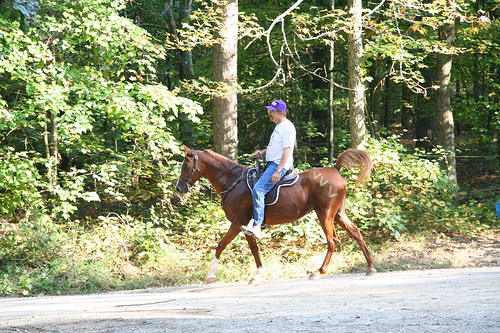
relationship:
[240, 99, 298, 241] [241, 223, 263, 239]
man has shoe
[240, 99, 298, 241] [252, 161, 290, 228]
man has leg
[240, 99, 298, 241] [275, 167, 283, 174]
man wearing watch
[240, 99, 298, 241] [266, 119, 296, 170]
man wearing shirt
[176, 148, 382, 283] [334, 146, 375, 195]
horse has tail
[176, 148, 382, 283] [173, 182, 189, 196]
horse has nose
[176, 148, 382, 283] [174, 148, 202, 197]
horse has head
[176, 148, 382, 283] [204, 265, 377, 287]
horse has hooves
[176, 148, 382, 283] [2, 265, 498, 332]
horse on gravel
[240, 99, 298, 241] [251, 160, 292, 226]
man wearing jeans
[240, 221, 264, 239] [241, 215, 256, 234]
foot in stirrups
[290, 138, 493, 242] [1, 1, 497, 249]
bushes in forest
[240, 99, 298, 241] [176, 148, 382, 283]
man on top of horse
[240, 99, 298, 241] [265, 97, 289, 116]
man wearing cap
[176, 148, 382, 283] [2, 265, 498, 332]
horse on top of gravel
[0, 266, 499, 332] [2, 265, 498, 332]
road made of gravel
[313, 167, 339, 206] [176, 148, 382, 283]
pattern on horse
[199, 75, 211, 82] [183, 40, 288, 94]
leaf on branch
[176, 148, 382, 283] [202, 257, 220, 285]
horse has hoof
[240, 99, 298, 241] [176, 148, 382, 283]
man riding on horse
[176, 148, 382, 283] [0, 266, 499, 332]
horse on top of road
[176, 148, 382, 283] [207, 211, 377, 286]
horse has legs